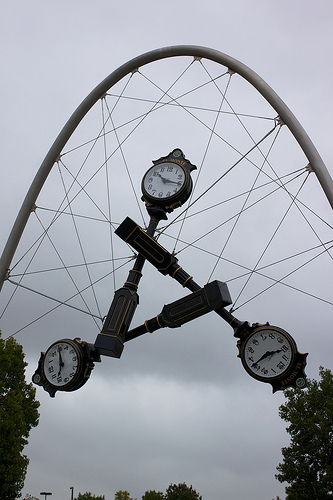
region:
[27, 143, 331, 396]
three clocks caught in a web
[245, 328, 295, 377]
clocks have white faces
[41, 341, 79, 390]
faces have black numbers and hands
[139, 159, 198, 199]
all clocks say the time is 10:15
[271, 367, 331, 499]
the side section of a tree top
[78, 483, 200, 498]
tips of distant tree tops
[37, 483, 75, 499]
tall overhead lights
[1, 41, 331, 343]
web of cables in an arch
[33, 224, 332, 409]
dark clouds moving in to area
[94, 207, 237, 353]
posts attached to the clocks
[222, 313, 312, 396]
clock facing upside down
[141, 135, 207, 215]
clock slanted to the right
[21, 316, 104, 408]
clock leaning to the left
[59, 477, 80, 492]
metal lamp pole in distance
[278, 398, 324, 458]
tree with green leaves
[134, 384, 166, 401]
light patch of blue sky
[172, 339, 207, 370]
dark grey clouds in sky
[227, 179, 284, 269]
dark metal wires supporting clocks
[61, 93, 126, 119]
large metal pole supporting clocks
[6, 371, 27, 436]
leafy green tree to left of photo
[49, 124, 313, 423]
three clocks are hanging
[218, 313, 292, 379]
the face of the clock is white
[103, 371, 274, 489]
the sky is overcast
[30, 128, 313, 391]
the clocks are hanging from wires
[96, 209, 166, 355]
the body of the clock is black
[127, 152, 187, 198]
the numbers on the clock are black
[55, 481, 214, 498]
the tops of the trees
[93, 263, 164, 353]
the clock has gold accents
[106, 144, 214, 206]
the clock says 10:15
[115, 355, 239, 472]
the clouds are thick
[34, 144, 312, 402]
Three clocks in the sculpture.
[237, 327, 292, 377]
Black numbers on the clock face.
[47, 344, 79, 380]
black hands on the clock.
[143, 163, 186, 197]
White face on the clock.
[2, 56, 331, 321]
Wire cables holding the clocks.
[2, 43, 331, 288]
Metal bar holding the cables.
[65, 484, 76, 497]
Street light in the background.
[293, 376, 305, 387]
Circle design on the clock.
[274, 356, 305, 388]
Writing on the clock.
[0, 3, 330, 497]
blue gray sky in the background.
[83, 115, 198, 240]
a clock on apole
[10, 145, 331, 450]
clocks on a pole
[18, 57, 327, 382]
clocks hangin from an arch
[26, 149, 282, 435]
three outside clocks on poles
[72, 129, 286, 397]
an outside clock on pole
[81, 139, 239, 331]
a small clock on pole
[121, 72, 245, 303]
a clock on a metal pole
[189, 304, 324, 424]
a small clock on a metal pole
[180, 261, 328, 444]
an outside clock on metal pole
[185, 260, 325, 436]
a pole with a small clock